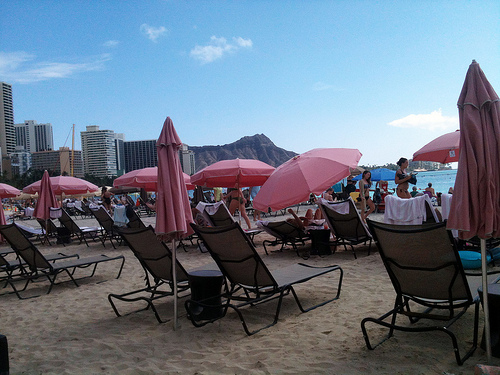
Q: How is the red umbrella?
A: Open.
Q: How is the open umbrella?
A: Red.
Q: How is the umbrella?
A: Closed.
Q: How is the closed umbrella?
A: Red.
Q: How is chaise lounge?
A: Vacant.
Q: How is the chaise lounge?
A: Black.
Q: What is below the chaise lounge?
A: White sand.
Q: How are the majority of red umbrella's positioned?
A: Open.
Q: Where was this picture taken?
A: Beach.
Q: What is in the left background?
A: Buildings.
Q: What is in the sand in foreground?
A: Footprints.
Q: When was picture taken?
A: Afternoon.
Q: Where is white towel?
A: Back of right lounge chair.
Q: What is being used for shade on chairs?
A: Umbrellas.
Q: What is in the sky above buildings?
A: Small clouds.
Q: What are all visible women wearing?
A: Bathing suits.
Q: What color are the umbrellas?
A: Red.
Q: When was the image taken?
A: Daytime.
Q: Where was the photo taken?
A: At the beach.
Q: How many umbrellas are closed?
A: 3.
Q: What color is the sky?
A: Blue.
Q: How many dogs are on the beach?
A: 0.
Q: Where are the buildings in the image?
A: On the left.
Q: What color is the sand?
A: Tan.